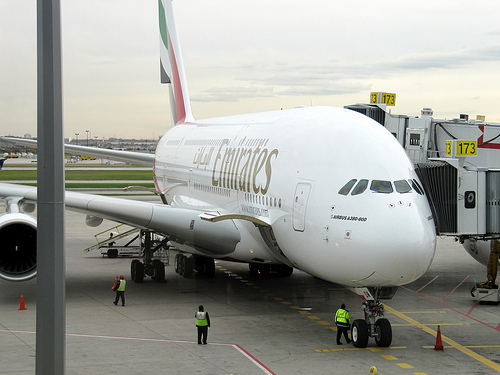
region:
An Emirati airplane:
[6, 87, 461, 340]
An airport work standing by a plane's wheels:
[325, 300, 357, 346]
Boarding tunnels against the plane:
[337, 90, 499, 241]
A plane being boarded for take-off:
[7, 65, 460, 325]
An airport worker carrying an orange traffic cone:
[103, 270, 135, 311]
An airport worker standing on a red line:
[190, 302, 214, 350]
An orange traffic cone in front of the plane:
[430, 320, 450, 356]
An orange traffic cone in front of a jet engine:
[13, 291, 30, 313]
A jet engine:
[0, 190, 54, 285]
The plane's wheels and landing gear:
[130, 244, 285, 284]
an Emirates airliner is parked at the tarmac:
[0, 1, 499, 374]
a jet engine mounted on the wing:
[1, 212, 42, 281]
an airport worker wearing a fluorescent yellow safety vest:
[333, 303, 353, 345]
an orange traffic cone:
[433, 323, 445, 348]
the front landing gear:
[351, 288, 393, 347]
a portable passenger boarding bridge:
[413, 156, 499, 236]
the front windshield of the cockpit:
[371, 179, 394, 196]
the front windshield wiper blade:
[371, 190, 393, 193]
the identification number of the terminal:
[456, 141, 476, 156]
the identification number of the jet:
[329, 211, 368, 222]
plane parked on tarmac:
[143, 102, 453, 327]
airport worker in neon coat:
[327, 297, 354, 347]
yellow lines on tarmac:
[450, 333, 488, 373]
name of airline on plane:
[203, 133, 279, 197]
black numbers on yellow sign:
[451, 139, 477, 156]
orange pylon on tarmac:
[426, 321, 454, 355]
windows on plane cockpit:
[337, 173, 428, 205]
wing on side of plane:
[71, 186, 238, 251]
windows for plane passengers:
[194, 180, 287, 213]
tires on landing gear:
[345, 316, 403, 353]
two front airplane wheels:
[348, 316, 397, 351]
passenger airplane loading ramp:
[416, 167, 498, 238]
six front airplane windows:
[336, 176, 427, 198]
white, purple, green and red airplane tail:
[150, 0, 193, 122]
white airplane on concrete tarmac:
[1, 0, 438, 350]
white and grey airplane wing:
[1, 179, 261, 274]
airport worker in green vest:
[192, 302, 213, 348]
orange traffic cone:
[15, 292, 30, 312]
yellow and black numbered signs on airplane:
[439, 137, 479, 157]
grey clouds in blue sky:
[196, 83, 276, 105]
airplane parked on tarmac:
[91, 91, 448, 296]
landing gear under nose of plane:
[350, 280, 409, 352]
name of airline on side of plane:
[206, 133, 281, 202]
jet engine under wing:
[0, 208, 38, 273]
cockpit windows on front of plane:
[343, 174, 420, 201]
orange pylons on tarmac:
[426, 321, 451, 353]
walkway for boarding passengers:
[415, 154, 497, 246]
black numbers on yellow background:
[448, 137, 481, 159]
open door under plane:
[216, 213, 295, 275]